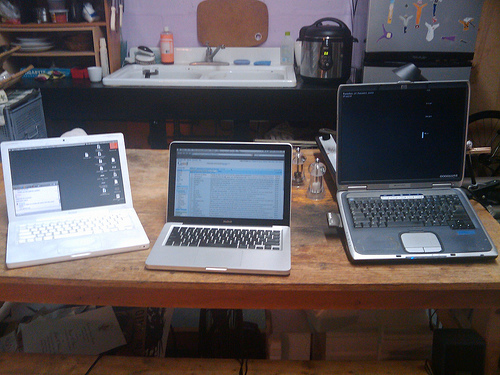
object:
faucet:
[201, 43, 228, 60]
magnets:
[377, 4, 484, 51]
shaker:
[292, 146, 307, 188]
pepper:
[288, 172, 306, 184]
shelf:
[1, 4, 108, 28]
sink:
[105, 44, 298, 88]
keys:
[163, 225, 281, 251]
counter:
[19, 66, 104, 90]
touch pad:
[397, 230, 445, 254]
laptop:
[0, 130, 153, 270]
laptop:
[145, 137, 293, 277]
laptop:
[327, 75, 498, 265]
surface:
[2, 144, 500, 286]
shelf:
[2, 23, 105, 69]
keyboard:
[163, 220, 283, 249]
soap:
[231, 55, 256, 66]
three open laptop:
[1, 75, 487, 298]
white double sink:
[102, 42, 296, 90]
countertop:
[0, 146, 500, 307]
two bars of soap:
[229, 54, 275, 68]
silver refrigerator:
[365, 0, 477, 83]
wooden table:
[0, 142, 498, 375]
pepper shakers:
[301, 159, 334, 198]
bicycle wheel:
[467, 112, 500, 180]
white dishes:
[11, 45, 56, 52]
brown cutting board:
[195, 4, 269, 50]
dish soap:
[188, 47, 229, 65]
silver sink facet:
[92, 46, 307, 89]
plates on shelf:
[5, 33, 60, 55]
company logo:
[458, 225, 486, 240]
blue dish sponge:
[255, 57, 278, 67]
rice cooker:
[292, 13, 359, 84]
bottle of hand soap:
[158, 27, 176, 63]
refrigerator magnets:
[367, 0, 482, 52]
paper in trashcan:
[264, 119, 325, 144]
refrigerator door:
[367, 2, 483, 57]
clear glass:
[309, 148, 325, 196]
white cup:
[83, 64, 107, 85]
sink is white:
[100, 45, 295, 96]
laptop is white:
[1, 131, 155, 268]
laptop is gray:
[142, 136, 293, 277]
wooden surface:
[0, 148, 498, 314]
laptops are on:
[0, 128, 151, 270]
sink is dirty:
[106, 47, 294, 98]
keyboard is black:
[165, 223, 286, 253]